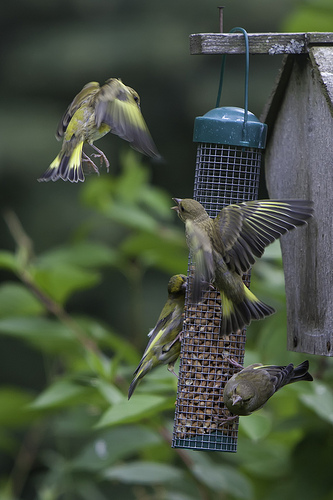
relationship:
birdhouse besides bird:
[188, 28, 331, 360] [38, 76, 157, 188]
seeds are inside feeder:
[174, 276, 243, 435] [162, 109, 281, 455]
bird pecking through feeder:
[127, 268, 188, 399] [191, 104, 269, 207]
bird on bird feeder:
[221, 361, 315, 421] [171, 108, 265, 452]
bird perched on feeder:
[38, 76, 157, 188] [167, 25, 268, 455]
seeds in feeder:
[174, 276, 243, 435] [167, 25, 268, 455]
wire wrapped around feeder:
[166, 141, 256, 451] [167, 25, 268, 455]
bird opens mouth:
[149, 181, 315, 297] [166, 191, 180, 211]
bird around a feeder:
[38, 76, 157, 188] [167, 25, 268, 455]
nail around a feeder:
[217, 5, 225, 33] [171, 106, 265, 456]